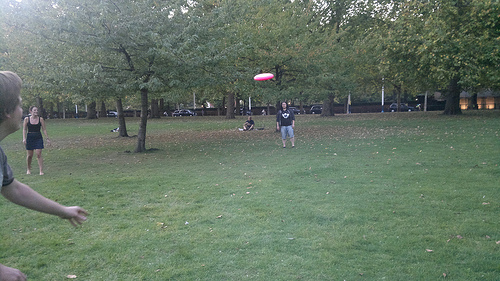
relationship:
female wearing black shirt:
[22, 106, 50, 176] [26, 116, 41, 132]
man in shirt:
[271, 96, 299, 150] [277, 107, 295, 127]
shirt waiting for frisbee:
[277, 107, 295, 127] [252, 69, 277, 86]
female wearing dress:
[22, 106, 50, 176] [25, 115, 45, 152]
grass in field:
[180, 126, 324, 243] [240, 142, 404, 234]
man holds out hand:
[2, 57, 90, 277] [61, 200, 89, 226]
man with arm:
[2, 57, 90, 277] [7, 173, 88, 227]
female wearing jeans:
[22, 106, 50, 176] [268, 122, 320, 157]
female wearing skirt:
[22, 106, 50, 176] [25, 130, 44, 150]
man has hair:
[2, 57, 90, 277] [0, 71, 24, 121]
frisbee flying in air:
[237, 69, 277, 89] [229, 67, 251, 99]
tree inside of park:
[82, 17, 216, 163] [17, 0, 494, 276]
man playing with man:
[2, 57, 90, 277] [262, 102, 315, 147]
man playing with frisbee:
[2, 57, 90, 277] [249, 65, 275, 82]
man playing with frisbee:
[262, 102, 315, 147] [249, 65, 275, 82]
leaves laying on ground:
[76, 125, 406, 164] [171, 129, 263, 279]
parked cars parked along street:
[102, 101, 416, 117] [204, 113, 225, 120]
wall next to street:
[118, 55, 489, 173] [310, 111, 388, 115]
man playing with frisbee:
[276, 102, 295, 148] [248, 64, 275, 89]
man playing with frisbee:
[0, 70, 90, 281] [248, 64, 275, 89]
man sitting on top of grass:
[243, 116, 255, 131] [233, 130, 265, 150]